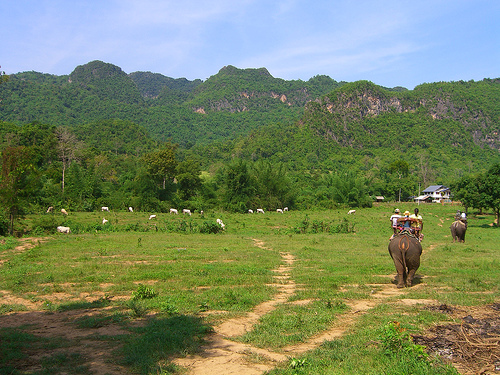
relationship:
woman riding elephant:
[410, 207, 422, 219] [388, 233, 423, 291]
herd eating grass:
[44, 204, 357, 235] [2, 200, 500, 373]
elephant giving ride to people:
[450, 220, 467, 244] [453, 211, 467, 222]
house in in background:
[414, 183, 452, 204] [3, 0, 496, 210]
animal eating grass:
[168, 208, 180, 215] [2, 200, 500, 373]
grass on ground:
[110, 313, 214, 367] [2, 200, 500, 373]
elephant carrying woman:
[388, 233, 423, 291] [410, 207, 422, 219]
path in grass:
[208, 234, 301, 339] [2, 200, 500, 373]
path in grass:
[278, 238, 447, 357] [2, 200, 500, 373]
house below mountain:
[414, 183, 452, 204] [3, 60, 499, 145]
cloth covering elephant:
[392, 229, 422, 249] [388, 233, 423, 291]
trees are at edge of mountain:
[3, 119, 418, 208] [3, 60, 499, 145]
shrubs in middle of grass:
[31, 217, 356, 235] [2, 200, 500, 373]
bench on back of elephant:
[392, 217, 421, 233] [388, 233, 423, 291]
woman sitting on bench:
[410, 207, 422, 219] [392, 217, 421, 233]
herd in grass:
[44, 204, 357, 235] [2, 200, 500, 373]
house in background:
[414, 183, 452, 204] [3, 0, 496, 210]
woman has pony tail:
[410, 207, 422, 219] [415, 210, 418, 216]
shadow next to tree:
[467, 222, 495, 229] [476, 159, 500, 229]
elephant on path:
[388, 233, 423, 291] [278, 238, 447, 357]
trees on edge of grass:
[3, 119, 418, 208] [2, 200, 500, 373]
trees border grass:
[3, 119, 418, 208] [2, 200, 500, 373]